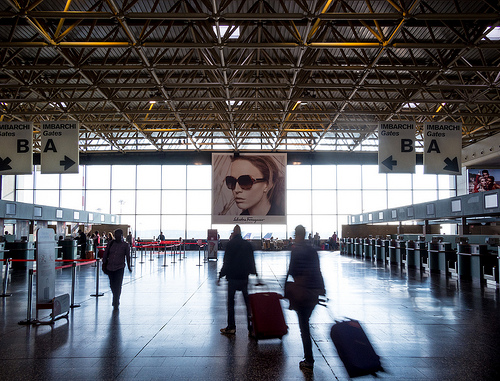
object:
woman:
[225, 154, 286, 215]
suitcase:
[243, 291, 287, 343]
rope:
[0, 258, 98, 272]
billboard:
[210, 153, 287, 225]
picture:
[208, 151, 287, 225]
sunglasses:
[225, 174, 270, 191]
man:
[217, 224, 259, 338]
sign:
[377, 121, 416, 175]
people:
[98, 229, 133, 310]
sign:
[423, 120, 461, 175]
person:
[283, 224, 329, 372]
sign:
[1, 122, 32, 176]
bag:
[328, 317, 381, 381]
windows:
[12, 161, 472, 240]